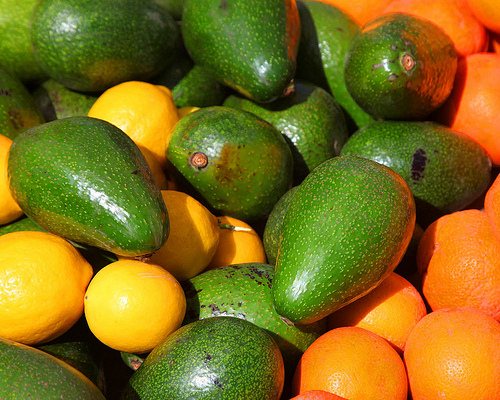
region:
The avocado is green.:
[9, 110, 174, 265]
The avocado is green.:
[268, 153, 417, 333]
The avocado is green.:
[160, 96, 298, 220]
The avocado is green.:
[341, 7, 466, 123]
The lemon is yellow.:
[78, 253, 193, 360]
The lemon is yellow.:
[0, 228, 95, 358]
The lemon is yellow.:
[80, 73, 185, 174]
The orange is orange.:
[286, 325, 410, 398]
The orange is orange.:
[390, 298, 499, 397]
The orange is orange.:
[413, 206, 499, 321]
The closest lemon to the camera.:
[1, 232, 96, 346]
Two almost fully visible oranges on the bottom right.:
[291, 305, 498, 398]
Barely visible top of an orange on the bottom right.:
[283, 388, 345, 398]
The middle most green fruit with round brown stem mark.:
[163, 104, 296, 219]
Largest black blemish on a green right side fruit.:
[411, 147, 428, 184]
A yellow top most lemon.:
[85, 82, 176, 169]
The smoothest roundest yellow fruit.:
[83, 259, 186, 356]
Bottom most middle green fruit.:
[117, 314, 284, 399]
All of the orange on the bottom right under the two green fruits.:
[288, 210, 499, 398]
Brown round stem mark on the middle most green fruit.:
[191, 148, 209, 168]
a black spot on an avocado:
[409, 146, 429, 184]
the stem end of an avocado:
[188, 146, 210, 170]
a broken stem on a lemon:
[213, 219, 253, 234]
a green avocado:
[6, 123, 171, 253]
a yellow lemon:
[0, 226, 94, 337]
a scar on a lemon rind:
[137, 267, 178, 285]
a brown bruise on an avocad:
[210, 140, 244, 180]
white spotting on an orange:
[406, 306, 498, 348]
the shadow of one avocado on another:
[295, 3, 330, 95]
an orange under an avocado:
[331, 273, 428, 342]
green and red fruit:
[20, 68, 280, 305]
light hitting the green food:
[54, 148, 119, 215]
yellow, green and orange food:
[90, 132, 441, 374]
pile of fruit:
[36, 15, 469, 311]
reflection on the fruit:
[409, 44, 458, 96]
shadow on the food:
[143, 142, 193, 184]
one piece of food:
[316, 324, 401, 399]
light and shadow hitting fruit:
[47, 23, 449, 345]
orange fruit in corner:
[438, 3, 493, 52]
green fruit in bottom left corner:
[13, 350, 76, 396]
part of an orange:
[341, 331, 378, 383]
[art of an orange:
[382, 301, 412, 343]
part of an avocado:
[221, 310, 234, 325]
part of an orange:
[420, 313, 464, 382]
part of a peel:
[246, 360, 277, 396]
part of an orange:
[368, 329, 385, 349]